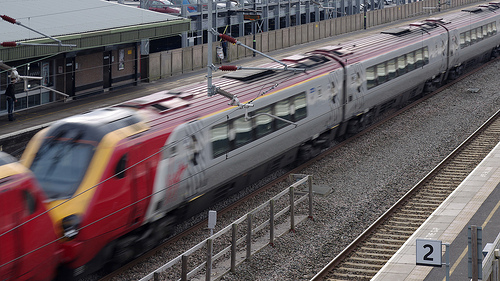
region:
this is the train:
[30, 70, 271, 230]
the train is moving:
[59, 92, 239, 244]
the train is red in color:
[67, 145, 126, 228]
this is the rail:
[349, 213, 395, 241]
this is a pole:
[199, 17, 230, 84]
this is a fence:
[261, 185, 308, 229]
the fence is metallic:
[215, 197, 273, 257]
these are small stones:
[366, 139, 403, 184]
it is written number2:
[414, 236, 440, 263]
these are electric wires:
[52, 190, 89, 240]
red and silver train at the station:
[20, 0, 496, 265]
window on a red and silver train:
[26, 138, 94, 204]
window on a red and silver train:
[211, 119, 233, 164]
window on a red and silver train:
[229, 112, 253, 150]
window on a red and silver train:
[251, 102, 275, 138]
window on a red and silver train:
[272, 97, 293, 130]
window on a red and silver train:
[290, 89, 312, 125]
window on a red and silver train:
[364, 62, 377, 89]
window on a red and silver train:
[374, 61, 386, 88]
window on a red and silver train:
[385, 57, 396, 83]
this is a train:
[181, 103, 246, 187]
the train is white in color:
[280, 129, 295, 139]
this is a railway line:
[391, 177, 434, 248]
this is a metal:
[399, 162, 426, 208]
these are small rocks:
[365, 162, 384, 189]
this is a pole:
[203, 15, 220, 92]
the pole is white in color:
[205, 30, 222, 54]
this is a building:
[41, 10, 133, 55]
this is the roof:
[60, 12, 95, 31]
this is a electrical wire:
[146, 132, 188, 167]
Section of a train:
[40, 47, 345, 232]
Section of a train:
[70, 47, 356, 235]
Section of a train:
[39, 85, 241, 267]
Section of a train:
[197, 30, 345, 197]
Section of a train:
[289, 0, 480, 147]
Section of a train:
[46, 58, 243, 243]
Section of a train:
[40, 80, 185, 265]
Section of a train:
[68, 59, 288, 256]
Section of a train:
[195, 50, 367, 182]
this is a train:
[155, 97, 236, 182]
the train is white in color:
[188, 152, 227, 189]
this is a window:
[215, 122, 238, 142]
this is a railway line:
[332, 181, 408, 256]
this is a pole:
[196, 0, 217, 102]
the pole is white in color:
[196, 37, 218, 62]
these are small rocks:
[348, 171, 388, 231]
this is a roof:
[38, 12, 106, 42]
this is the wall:
[71, 50, 96, 88]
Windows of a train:
[202, 88, 312, 165]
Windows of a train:
[206, 89, 315, 163]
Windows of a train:
[356, 45, 434, 90]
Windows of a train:
[360, 48, 430, 90]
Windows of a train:
[453, 21, 495, 42]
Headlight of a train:
[60, 215, 85, 244]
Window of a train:
[31, 139, 91, 198]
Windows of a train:
[205, 103, 307, 157]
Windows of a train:
[361, 39, 432, 95]